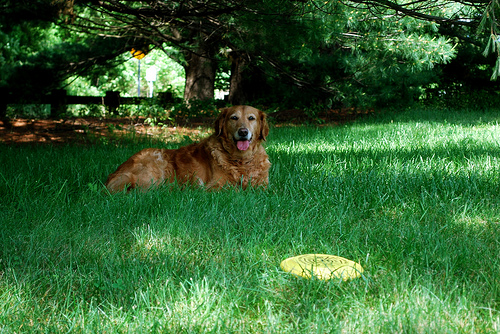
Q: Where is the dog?
A: In the grass.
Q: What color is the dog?
A: Brown.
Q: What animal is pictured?
A: Dog.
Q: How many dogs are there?
A: One.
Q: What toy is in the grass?
A: Frisbee.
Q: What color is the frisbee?
A: Yellow.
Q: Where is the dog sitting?
A: Grass.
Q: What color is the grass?
A: Green.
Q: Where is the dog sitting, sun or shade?
A: Shade.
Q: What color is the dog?
A: Brown.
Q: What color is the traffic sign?
A: Yellow.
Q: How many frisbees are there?
A: One.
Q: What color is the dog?
A: Brown.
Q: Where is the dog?
A: In the grass.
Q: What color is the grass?
A: Green.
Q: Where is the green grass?
A: In the field.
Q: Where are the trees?
A: Behind the dog.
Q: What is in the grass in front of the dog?
A: A frisbee.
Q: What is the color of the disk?
A: Yellow.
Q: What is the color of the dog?
A: Brown.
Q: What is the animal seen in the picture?
A: Dog.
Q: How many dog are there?
A: One.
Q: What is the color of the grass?
A: Green.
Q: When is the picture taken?
A: Daytime.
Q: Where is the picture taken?
A: At the park.